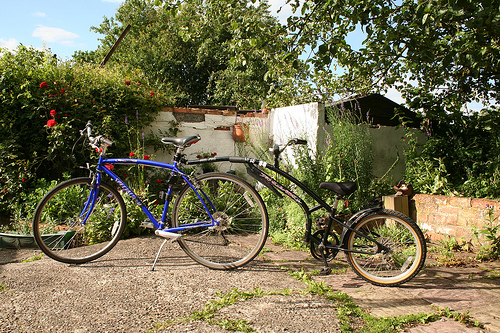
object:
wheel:
[171, 172, 269, 271]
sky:
[0, 0, 138, 61]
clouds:
[0, 0, 125, 60]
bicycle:
[31, 119, 428, 287]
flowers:
[36, 76, 172, 190]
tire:
[30, 175, 129, 264]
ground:
[1, 224, 500, 333]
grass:
[1, 251, 42, 262]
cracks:
[0, 230, 499, 333]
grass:
[292, 266, 313, 296]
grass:
[341, 293, 355, 328]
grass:
[191, 289, 297, 309]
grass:
[198, 310, 253, 329]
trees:
[0, 0, 500, 251]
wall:
[378, 186, 498, 258]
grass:
[282, 264, 399, 330]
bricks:
[442, 200, 465, 224]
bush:
[0, 42, 189, 209]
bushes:
[295, 94, 398, 216]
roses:
[39, 72, 107, 131]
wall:
[125, 91, 429, 193]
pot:
[232, 121, 248, 142]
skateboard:
[30, 120, 267, 277]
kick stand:
[149, 236, 167, 271]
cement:
[2, 229, 499, 332]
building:
[129, 92, 423, 187]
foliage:
[0, 0, 499, 249]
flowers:
[321, 88, 374, 185]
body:
[75, 154, 215, 234]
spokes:
[52, 221, 85, 257]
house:
[140, 89, 432, 192]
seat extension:
[161, 134, 425, 287]